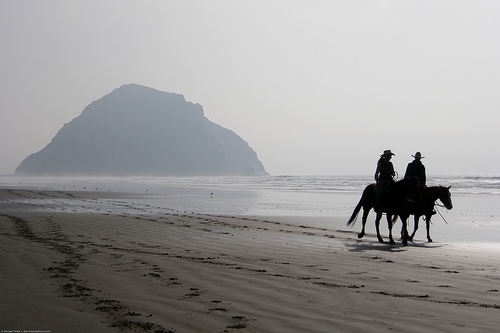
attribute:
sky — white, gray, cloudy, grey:
[3, 7, 499, 100]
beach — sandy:
[2, 208, 496, 332]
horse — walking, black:
[346, 179, 424, 246]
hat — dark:
[382, 148, 395, 157]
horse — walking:
[405, 184, 454, 240]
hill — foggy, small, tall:
[15, 77, 271, 185]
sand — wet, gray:
[2, 186, 162, 220]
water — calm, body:
[144, 165, 494, 190]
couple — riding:
[376, 148, 436, 189]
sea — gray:
[1, 168, 499, 204]